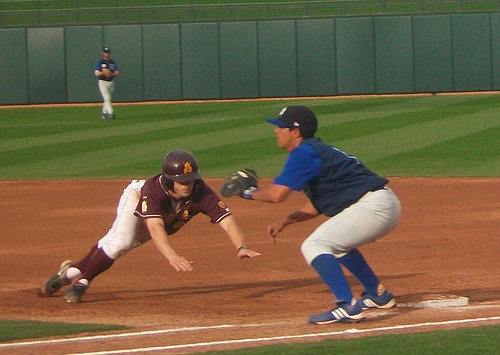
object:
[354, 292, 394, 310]
cleat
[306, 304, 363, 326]
cleat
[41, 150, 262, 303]
man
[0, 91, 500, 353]
field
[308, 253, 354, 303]
blue socks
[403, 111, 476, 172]
ground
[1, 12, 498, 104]
green fence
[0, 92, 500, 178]
outfield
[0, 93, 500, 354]
baseball field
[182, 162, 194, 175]
orange letter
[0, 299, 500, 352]
chalk line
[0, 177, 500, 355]
dirt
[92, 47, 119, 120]
player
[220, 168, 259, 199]
glove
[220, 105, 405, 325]
baseball player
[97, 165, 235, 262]
uniform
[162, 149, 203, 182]
helmet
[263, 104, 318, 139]
baseball cap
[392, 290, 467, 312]
base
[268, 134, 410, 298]
uniform